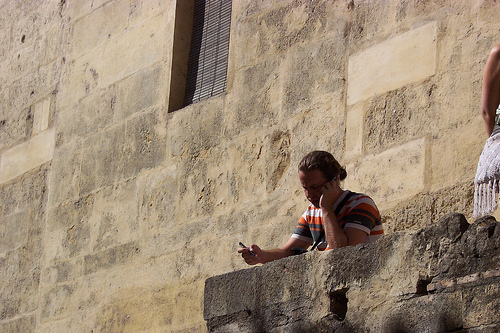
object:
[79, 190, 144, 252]
cement block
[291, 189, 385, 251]
shirt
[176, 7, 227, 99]
window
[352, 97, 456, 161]
wall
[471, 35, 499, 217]
woman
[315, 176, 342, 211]
hand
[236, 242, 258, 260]
phone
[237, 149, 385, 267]
man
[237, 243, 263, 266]
man hand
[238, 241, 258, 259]
pen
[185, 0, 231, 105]
blinds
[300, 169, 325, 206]
face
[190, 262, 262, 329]
stone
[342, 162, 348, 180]
ponytail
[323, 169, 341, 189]
cell phone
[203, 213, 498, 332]
balcony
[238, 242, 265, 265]
hand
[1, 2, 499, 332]
building